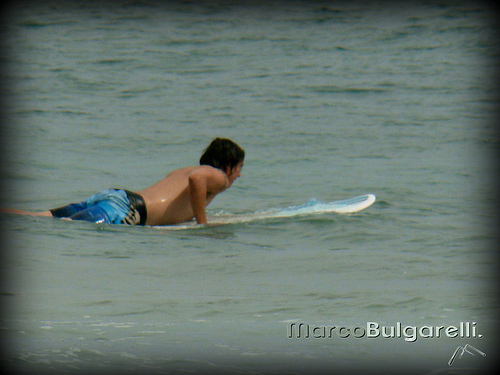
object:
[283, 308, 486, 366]
watermark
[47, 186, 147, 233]
short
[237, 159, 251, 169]
eyebrow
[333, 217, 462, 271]
ocean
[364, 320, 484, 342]
writing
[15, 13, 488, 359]
ocean waves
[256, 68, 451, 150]
scarf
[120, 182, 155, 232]
waist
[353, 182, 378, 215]
tip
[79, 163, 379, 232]
board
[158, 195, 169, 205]
light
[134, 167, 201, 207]
man`s back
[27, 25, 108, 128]
wave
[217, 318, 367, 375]
waves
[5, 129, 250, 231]
man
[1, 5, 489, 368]
sea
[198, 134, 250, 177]
hair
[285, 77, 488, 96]
wave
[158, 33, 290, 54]
wave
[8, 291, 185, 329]
wave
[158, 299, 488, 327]
wave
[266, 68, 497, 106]
wave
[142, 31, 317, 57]
wave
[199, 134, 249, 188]
head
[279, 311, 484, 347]
photographers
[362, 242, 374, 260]
part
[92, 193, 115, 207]
part